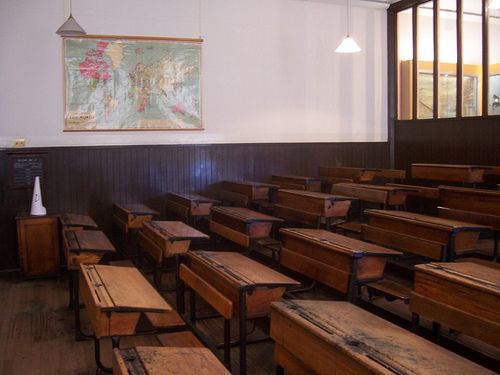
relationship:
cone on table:
[27, 166, 55, 216] [10, 214, 56, 283]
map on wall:
[58, 24, 208, 133] [1, 0, 392, 276]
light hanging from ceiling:
[333, 0, 365, 56] [311, 0, 396, 13]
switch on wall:
[11, 137, 26, 149] [2, 0, 391, 148]